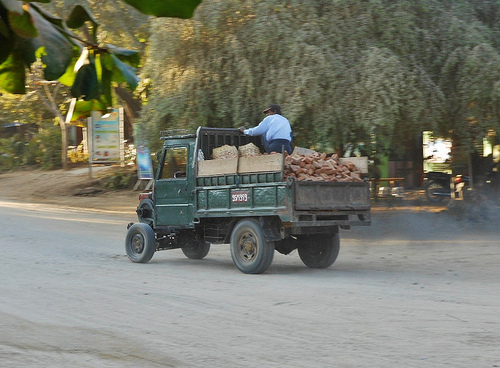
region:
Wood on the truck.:
[287, 152, 358, 177]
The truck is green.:
[155, 144, 266, 248]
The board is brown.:
[197, 152, 294, 174]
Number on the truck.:
[217, 182, 260, 207]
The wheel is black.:
[215, 220, 270, 271]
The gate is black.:
[285, 177, 377, 218]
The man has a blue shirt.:
[255, 117, 298, 142]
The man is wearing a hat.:
[256, 98, 290, 114]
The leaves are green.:
[28, 21, 114, 93]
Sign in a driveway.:
[76, 103, 134, 176]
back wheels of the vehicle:
[204, 210, 358, 278]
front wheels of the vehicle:
[102, 192, 225, 274]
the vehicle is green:
[87, 99, 390, 259]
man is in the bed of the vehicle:
[231, 81, 328, 178]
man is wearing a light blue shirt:
[233, 108, 311, 162]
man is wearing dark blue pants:
[263, 129, 311, 169]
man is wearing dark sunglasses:
[262, 97, 291, 118]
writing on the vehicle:
[220, 185, 258, 210]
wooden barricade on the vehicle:
[192, 138, 311, 188]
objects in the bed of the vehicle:
[209, 132, 377, 192]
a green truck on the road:
[115, 103, 392, 336]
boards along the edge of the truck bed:
[186, 147, 286, 188]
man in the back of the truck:
[205, 100, 370, 255]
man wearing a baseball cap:
[257, 101, 282, 117]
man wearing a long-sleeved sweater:
[240, 102, 296, 142]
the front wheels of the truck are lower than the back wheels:
[100, 206, 345, 281]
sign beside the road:
[70, 91, 138, 263]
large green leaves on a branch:
[0, 3, 146, 104]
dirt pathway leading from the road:
[1, 150, 121, 235]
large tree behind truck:
[135, 0, 495, 267]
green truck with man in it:
[111, 72, 396, 297]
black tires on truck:
[207, 224, 297, 278]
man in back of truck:
[238, 111, 317, 151]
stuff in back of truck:
[289, 148, 358, 185]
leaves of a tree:
[18, 35, 120, 101]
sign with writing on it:
[78, 115, 131, 185]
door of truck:
[150, 146, 197, 259]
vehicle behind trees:
[327, 133, 388, 175]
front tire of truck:
[120, 226, 177, 293]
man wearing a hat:
[243, 98, 308, 153]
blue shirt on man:
[265, 118, 310, 152]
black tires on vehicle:
[116, 221, 169, 263]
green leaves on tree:
[60, 73, 108, 110]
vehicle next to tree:
[345, 138, 381, 172]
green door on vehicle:
[156, 143, 198, 228]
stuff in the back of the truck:
[296, 150, 353, 184]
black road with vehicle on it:
[20, 230, 120, 307]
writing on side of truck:
[211, 186, 271, 212]